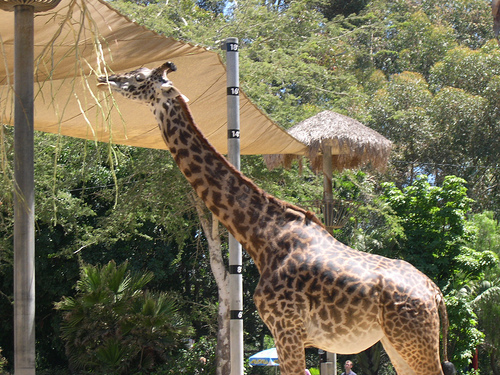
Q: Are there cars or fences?
A: No, there are no cars or fences.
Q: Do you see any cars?
A: No, there are no cars.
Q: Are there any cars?
A: No, there are no cars.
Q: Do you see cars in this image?
A: No, there are no cars.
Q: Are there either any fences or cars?
A: No, there are no cars or fences.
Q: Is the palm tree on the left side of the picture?
A: Yes, the palm tree is on the left of the image.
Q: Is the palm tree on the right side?
A: No, the palm tree is on the left of the image.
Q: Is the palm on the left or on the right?
A: The palm is on the left of the image.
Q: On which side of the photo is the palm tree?
A: The palm tree is on the left of the image.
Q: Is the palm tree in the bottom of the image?
A: Yes, the palm tree is in the bottom of the image.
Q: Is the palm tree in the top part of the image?
A: No, the palm tree is in the bottom of the image.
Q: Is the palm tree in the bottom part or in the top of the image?
A: The palm tree is in the bottom of the image.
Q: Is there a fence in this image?
A: No, there are no fences.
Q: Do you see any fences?
A: No, there are no fences.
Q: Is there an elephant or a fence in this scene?
A: No, there are no fences or elephants.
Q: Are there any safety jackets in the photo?
A: No, there are no safety jackets.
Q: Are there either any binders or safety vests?
A: No, there are no safety vests or binders.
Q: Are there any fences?
A: No, there are no fences.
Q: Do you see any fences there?
A: No, there are no fences.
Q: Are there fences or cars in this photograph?
A: No, there are no fences or cars.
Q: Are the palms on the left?
A: Yes, the palms are on the left of the image.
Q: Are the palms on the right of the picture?
A: No, the palms are on the left of the image.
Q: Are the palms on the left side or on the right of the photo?
A: The palms are on the left of the image.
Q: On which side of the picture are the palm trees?
A: The palm trees are on the left of the image.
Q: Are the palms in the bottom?
A: Yes, the palms are in the bottom of the image.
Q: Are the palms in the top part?
A: No, the palms are in the bottom of the image.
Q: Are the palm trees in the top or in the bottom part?
A: The palm trees are in the bottom of the image.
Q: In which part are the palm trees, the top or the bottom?
A: The palm trees are in the bottom of the image.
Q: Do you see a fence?
A: No, there are no fences.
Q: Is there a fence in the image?
A: No, there are no fences.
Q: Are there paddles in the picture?
A: No, there are no paddles.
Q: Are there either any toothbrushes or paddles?
A: No, there are no paddles or toothbrushes.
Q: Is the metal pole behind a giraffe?
A: Yes, the pole is behind a giraffe.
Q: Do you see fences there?
A: No, there are no fences.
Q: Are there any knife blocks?
A: No, there are no knife blocks.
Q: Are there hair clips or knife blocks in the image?
A: No, there are no knife blocks or hair clips.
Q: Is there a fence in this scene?
A: No, there are no fences.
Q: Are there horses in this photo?
A: No, there are no horses.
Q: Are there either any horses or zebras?
A: No, there are no horses or zebras.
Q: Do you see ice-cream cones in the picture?
A: No, there are no ice-cream cones.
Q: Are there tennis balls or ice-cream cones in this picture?
A: No, there are no ice-cream cones or tennis balls.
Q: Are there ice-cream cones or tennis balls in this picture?
A: No, there are no ice-cream cones or tennis balls.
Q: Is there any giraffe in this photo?
A: Yes, there is a giraffe.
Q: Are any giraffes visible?
A: Yes, there is a giraffe.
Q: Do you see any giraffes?
A: Yes, there is a giraffe.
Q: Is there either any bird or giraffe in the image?
A: Yes, there is a giraffe.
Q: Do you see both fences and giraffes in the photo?
A: No, there is a giraffe but no fences.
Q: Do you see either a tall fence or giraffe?
A: Yes, there is a tall giraffe.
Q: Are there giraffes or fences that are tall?
A: Yes, the giraffe is tall.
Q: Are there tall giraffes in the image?
A: Yes, there is a tall giraffe.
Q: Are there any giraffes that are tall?
A: Yes, there is a giraffe that is tall.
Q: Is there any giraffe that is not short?
A: Yes, there is a tall giraffe.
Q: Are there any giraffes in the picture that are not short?
A: Yes, there is a tall giraffe.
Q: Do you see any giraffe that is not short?
A: Yes, there is a tall giraffe.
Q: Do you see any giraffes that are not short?
A: Yes, there is a tall giraffe.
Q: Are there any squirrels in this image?
A: No, there are no squirrels.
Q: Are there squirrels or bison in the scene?
A: No, there are no squirrels or bison.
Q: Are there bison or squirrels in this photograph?
A: No, there are no squirrels or bison.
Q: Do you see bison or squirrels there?
A: No, there are no squirrels or bison.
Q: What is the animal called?
A: The animal is a giraffe.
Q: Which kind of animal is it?
A: The animal is a giraffe.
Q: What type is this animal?
A: This is a giraffe.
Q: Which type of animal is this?
A: This is a giraffe.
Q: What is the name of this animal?
A: This is a giraffe.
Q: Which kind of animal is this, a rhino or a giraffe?
A: This is a giraffe.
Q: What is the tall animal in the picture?
A: The animal is a giraffe.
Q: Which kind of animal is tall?
A: The animal is a giraffe.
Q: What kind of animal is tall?
A: The animal is a giraffe.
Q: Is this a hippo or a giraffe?
A: This is a giraffe.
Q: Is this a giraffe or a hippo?
A: This is a giraffe.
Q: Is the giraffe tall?
A: Yes, the giraffe is tall.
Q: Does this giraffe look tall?
A: Yes, the giraffe is tall.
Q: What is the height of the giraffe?
A: The giraffe is tall.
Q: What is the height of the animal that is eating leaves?
A: The giraffe is tall.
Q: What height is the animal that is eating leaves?
A: The giraffe is tall.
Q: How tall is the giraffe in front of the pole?
A: The giraffe is tall.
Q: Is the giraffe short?
A: No, the giraffe is tall.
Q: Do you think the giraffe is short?
A: No, the giraffe is tall.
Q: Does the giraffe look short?
A: No, the giraffe is tall.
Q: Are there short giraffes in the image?
A: No, there is a giraffe but it is tall.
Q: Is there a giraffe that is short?
A: No, there is a giraffe but it is tall.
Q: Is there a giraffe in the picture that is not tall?
A: No, there is a giraffe but it is tall.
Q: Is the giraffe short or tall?
A: The giraffe is tall.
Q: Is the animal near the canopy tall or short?
A: The giraffe is tall.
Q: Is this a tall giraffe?
A: Yes, this is a tall giraffe.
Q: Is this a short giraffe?
A: No, this is a tall giraffe.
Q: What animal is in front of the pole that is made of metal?
A: The giraffe is in front of the pole.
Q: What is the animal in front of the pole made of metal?
A: The animal is a giraffe.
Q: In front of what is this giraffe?
A: The giraffe is in front of the pole.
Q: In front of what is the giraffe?
A: The giraffe is in front of the pole.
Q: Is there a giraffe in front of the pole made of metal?
A: Yes, there is a giraffe in front of the pole.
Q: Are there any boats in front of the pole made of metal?
A: No, there is a giraffe in front of the pole.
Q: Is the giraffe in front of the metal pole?
A: Yes, the giraffe is in front of the pole.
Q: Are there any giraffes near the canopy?
A: Yes, there is a giraffe near the canopy.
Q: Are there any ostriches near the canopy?
A: No, there is a giraffe near the canopy.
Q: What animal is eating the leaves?
A: The animal is a giraffe.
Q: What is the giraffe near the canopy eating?
A: The giraffe is eating leaves.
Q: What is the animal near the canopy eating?
A: The giraffe is eating leaves.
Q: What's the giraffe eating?
A: The giraffe is eating leaves.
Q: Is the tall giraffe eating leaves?
A: Yes, the giraffe is eating leaves.